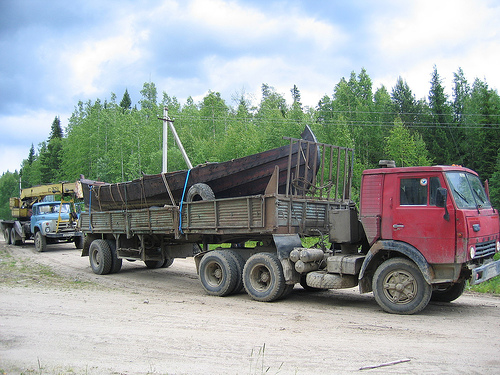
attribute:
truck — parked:
[80, 162, 499, 305]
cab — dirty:
[330, 162, 499, 309]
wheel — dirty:
[371, 258, 429, 311]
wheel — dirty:
[243, 252, 283, 302]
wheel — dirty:
[195, 251, 240, 294]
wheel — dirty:
[87, 237, 111, 278]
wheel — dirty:
[433, 271, 470, 309]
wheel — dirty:
[145, 247, 166, 268]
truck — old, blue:
[1, 188, 83, 254]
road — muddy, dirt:
[0, 226, 499, 374]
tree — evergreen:
[46, 116, 61, 189]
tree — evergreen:
[22, 146, 36, 189]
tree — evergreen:
[413, 71, 470, 173]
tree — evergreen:
[454, 82, 499, 179]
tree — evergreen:
[344, 69, 381, 183]